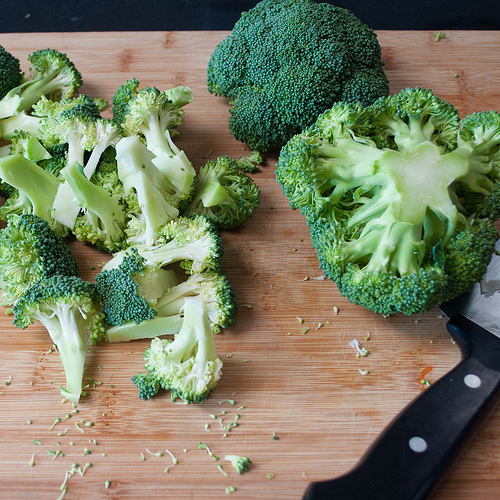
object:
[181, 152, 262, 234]
broccoli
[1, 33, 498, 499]
board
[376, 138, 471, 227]
stock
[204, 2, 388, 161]
head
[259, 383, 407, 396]
lines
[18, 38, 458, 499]
wood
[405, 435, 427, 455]
circle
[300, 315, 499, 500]
handle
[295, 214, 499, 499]
knife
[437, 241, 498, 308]
blade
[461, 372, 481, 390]
dot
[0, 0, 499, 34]
table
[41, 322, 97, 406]
stem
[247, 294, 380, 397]
spot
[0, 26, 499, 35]
edge